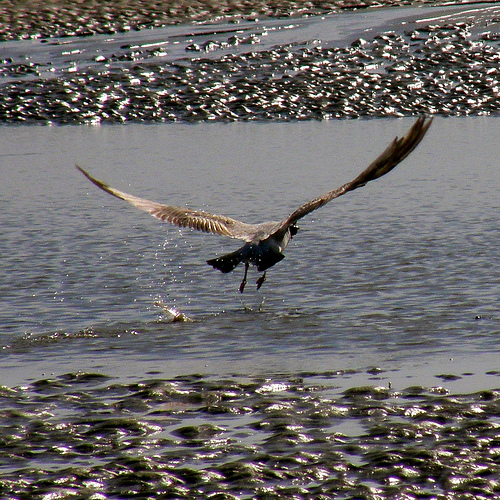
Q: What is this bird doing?
A: Lowering itself to catch a fish.